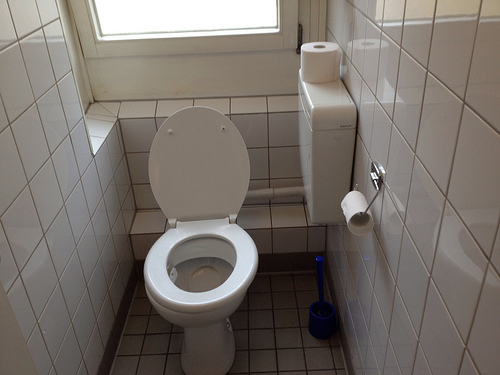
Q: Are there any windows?
A: Yes, there is a window.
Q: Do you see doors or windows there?
A: Yes, there is a window.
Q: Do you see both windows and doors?
A: No, there is a window but no doors.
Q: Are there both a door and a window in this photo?
A: No, there is a window but no doors.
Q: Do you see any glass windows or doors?
A: Yes, there is a glass window.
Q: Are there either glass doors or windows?
A: Yes, there is a glass window.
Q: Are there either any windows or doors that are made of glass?
A: Yes, the window is made of glass.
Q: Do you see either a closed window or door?
A: Yes, there is a closed window.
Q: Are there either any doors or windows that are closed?
A: Yes, the window is closed.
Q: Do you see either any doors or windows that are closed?
A: Yes, the window is closed.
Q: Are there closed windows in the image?
A: Yes, there is a closed window.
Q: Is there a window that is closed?
A: Yes, there is a window that is closed.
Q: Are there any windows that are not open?
A: Yes, there is an closed window.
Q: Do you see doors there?
A: No, there are no doors.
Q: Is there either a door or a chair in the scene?
A: No, there are no doors or chairs.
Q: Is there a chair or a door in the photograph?
A: No, there are no doors or chairs.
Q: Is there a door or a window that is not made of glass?
A: No, there is a window but it is made of glass.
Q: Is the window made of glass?
A: Yes, the window is made of glass.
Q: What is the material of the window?
A: The window is made of glass.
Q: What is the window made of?
A: The window is made of glass.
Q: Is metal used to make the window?
A: No, the window is made of glass.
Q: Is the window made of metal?
A: No, the window is made of glass.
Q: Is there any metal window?
A: No, there is a window but it is made of glass.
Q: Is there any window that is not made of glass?
A: No, there is a window but it is made of glass.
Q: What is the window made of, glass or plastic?
A: The window is made of glass.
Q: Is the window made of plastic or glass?
A: The window is made of glass.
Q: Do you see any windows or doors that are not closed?
A: No, there is a window but it is closed.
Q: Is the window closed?
A: Yes, the window is closed.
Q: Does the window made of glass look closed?
A: Yes, the window is closed.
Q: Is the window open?
A: No, the window is closed.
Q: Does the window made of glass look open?
A: No, the window is closed.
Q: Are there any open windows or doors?
A: No, there is a window but it is closed.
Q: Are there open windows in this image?
A: No, there is a window but it is closed.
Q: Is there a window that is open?
A: No, there is a window but it is closed.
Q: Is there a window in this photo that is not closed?
A: No, there is a window but it is closed.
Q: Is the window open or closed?
A: The window is closed.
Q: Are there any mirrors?
A: No, there are no mirrors.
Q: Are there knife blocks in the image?
A: No, there are no knife blocks.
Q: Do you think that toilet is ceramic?
A: Yes, the toilet is ceramic.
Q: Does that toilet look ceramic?
A: Yes, the toilet is ceramic.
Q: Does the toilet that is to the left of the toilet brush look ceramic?
A: Yes, the toilet is ceramic.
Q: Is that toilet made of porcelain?
A: Yes, the toilet is made of porcelain.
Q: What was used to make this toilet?
A: The toilet is made of porcelain.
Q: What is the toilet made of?
A: The toilet is made of porcelain.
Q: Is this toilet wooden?
A: No, the toilet is ceramic.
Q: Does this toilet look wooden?
A: No, the toilet is ceramic.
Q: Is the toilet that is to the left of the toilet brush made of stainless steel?
A: No, the toilet is made of porcelain.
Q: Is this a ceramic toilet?
A: Yes, this is a ceramic toilet.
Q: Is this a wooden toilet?
A: No, this is a ceramic toilet.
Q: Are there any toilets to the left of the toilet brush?
A: Yes, there is a toilet to the left of the toilet brush.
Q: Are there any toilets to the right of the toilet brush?
A: No, the toilet is to the left of the toilet brush.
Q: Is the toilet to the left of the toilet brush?
A: Yes, the toilet is to the left of the toilet brush.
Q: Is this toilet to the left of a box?
A: No, the toilet is to the left of the toilet brush.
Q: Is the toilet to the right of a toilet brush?
A: No, the toilet is to the left of a toilet brush.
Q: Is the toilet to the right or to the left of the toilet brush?
A: The toilet is to the left of the toilet brush.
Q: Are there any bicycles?
A: No, there are no bicycles.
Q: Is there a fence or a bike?
A: No, there are no bikes or fences.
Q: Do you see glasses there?
A: No, there are no glasses.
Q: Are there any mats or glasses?
A: No, there are no glasses or mats.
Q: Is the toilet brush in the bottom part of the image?
A: Yes, the toilet brush is in the bottom of the image.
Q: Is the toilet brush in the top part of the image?
A: No, the toilet brush is in the bottom of the image.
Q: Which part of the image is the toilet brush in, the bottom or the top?
A: The toilet brush is in the bottom of the image.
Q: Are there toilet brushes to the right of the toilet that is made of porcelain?
A: Yes, there is a toilet brush to the right of the toilet.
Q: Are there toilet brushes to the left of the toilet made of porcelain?
A: No, the toilet brush is to the right of the toilet.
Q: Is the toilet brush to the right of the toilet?
A: Yes, the toilet brush is to the right of the toilet.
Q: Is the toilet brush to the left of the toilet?
A: No, the toilet brush is to the right of the toilet.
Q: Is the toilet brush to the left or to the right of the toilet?
A: The toilet brush is to the right of the toilet.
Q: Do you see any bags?
A: No, there are no bags.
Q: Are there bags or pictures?
A: No, there are no bags or pictures.